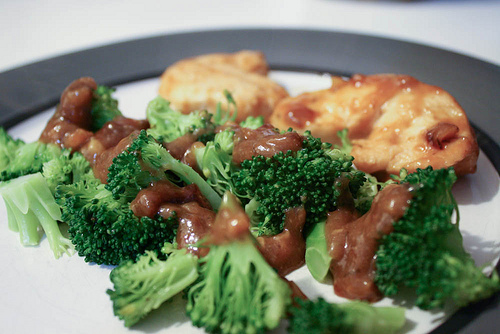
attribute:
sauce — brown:
[42, 92, 434, 307]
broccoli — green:
[185, 187, 292, 332]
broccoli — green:
[53, 178, 173, 265]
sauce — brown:
[127, 180, 259, 277]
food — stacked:
[2, 29, 498, 329]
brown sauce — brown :
[36, 77, 414, 305]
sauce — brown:
[33, 72, 428, 311]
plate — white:
[2, 248, 107, 328]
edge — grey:
[0, 26, 498, 163]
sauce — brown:
[289, 168, 419, 286]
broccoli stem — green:
[9, 174, 66, 253]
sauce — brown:
[218, 102, 303, 189]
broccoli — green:
[57, 175, 180, 263]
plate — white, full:
[6, 26, 498, 333]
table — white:
[2, 12, 499, 166]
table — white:
[9, 0, 494, 60]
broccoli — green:
[66, 186, 277, 331]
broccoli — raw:
[361, 180, 497, 295]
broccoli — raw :
[6, 82, 476, 332]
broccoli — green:
[50, 141, 169, 244]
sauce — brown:
[235, 117, 287, 152]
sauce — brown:
[331, 228, 358, 260]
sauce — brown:
[337, 230, 371, 269]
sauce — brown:
[236, 137, 283, 154]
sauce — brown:
[340, 227, 370, 262]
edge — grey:
[25, 55, 152, 74]